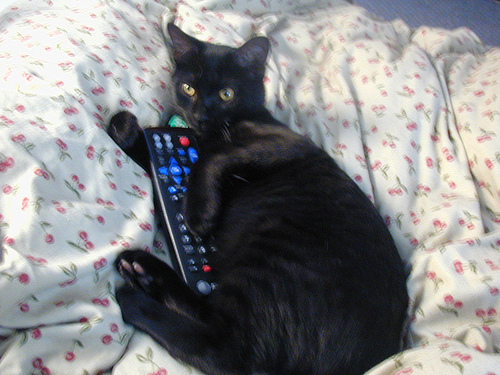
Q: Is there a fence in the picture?
A: No, there are no fences.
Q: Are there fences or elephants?
A: No, there are no fences or elephants.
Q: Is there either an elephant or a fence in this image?
A: No, there are no fences or elephants.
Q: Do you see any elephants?
A: No, there are no elephants.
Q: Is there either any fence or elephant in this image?
A: No, there are no elephants or fences.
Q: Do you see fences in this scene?
A: No, there are no fences.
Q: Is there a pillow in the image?
A: No, there are no pillows.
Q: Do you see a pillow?
A: No, there are no pillows.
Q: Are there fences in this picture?
A: No, there are no fences.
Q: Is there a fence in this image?
A: No, there are no fences.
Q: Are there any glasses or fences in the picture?
A: No, there are no fences or glasses.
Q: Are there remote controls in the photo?
A: Yes, there is a remote control.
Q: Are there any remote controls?
A: Yes, there is a remote control.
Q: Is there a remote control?
A: Yes, there is a remote control.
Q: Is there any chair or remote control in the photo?
A: Yes, there is a remote control.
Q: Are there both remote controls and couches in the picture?
A: No, there is a remote control but no couches.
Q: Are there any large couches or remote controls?
A: Yes, there is a large remote control.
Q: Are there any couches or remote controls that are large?
A: Yes, the remote control is large.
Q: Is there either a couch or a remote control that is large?
A: Yes, the remote control is large.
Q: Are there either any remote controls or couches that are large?
A: Yes, the remote control is large.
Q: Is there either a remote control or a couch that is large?
A: Yes, the remote control is large.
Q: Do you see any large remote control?
A: Yes, there is a large remote control.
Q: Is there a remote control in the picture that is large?
A: Yes, there is a remote control that is large.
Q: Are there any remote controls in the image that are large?
A: Yes, there is a remote control that is large.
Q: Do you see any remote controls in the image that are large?
A: Yes, there is a remote control that is large.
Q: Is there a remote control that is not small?
A: Yes, there is a large remote control.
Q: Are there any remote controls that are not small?
A: Yes, there is a large remote control.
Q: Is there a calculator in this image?
A: No, there are no calculators.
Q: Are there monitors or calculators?
A: No, there are no calculators or monitors.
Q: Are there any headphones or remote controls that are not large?
A: No, there is a remote control but it is large.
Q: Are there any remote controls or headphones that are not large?
A: No, there is a remote control but it is large.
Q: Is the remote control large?
A: Yes, the remote control is large.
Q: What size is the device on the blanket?
A: The remote is large.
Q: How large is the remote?
A: The remote is large.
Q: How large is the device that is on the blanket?
A: The remote is large.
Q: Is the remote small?
A: No, the remote is large.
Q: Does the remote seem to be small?
A: No, the remote is large.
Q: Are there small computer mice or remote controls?
A: No, there is a remote control but it is large.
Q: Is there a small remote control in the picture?
A: No, there is a remote control but it is large.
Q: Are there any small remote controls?
A: No, there is a remote control but it is large.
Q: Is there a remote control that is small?
A: No, there is a remote control but it is large.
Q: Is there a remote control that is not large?
A: No, there is a remote control but it is large.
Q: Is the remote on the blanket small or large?
A: The remote is large.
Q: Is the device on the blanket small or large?
A: The remote is large.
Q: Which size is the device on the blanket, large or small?
A: The remote is large.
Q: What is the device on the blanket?
A: The device is a remote control.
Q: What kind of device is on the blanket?
A: The device is a remote control.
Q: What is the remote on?
A: The remote is on the blanket.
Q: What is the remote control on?
A: The remote is on the blanket.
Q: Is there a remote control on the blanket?
A: Yes, there is a remote control on the blanket.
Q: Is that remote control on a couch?
A: No, the remote control is on the blanket.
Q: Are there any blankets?
A: Yes, there is a blanket.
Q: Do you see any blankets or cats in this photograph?
A: Yes, there is a blanket.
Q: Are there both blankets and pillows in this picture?
A: No, there is a blanket but no pillows.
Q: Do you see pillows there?
A: No, there are no pillows.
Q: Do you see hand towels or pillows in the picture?
A: No, there are no pillows or hand towels.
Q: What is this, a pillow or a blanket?
A: This is a blanket.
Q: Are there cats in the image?
A: Yes, there is a cat.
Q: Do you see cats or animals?
A: Yes, there is a cat.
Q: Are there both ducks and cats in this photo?
A: No, there is a cat but no ducks.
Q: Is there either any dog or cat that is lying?
A: Yes, the cat is lying.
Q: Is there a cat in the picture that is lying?
A: Yes, there is a cat that is lying.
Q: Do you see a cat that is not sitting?
A: Yes, there is a cat that is lying .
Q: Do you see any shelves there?
A: No, there are no shelves.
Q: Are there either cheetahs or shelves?
A: No, there are no shelves or cheetahs.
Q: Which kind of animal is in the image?
A: The animal is a cat.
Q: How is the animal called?
A: The animal is a cat.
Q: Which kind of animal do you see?
A: The animal is a cat.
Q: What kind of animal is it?
A: The animal is a cat.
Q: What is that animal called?
A: This is a cat.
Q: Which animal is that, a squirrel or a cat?
A: This is a cat.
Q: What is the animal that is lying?
A: The animal is a cat.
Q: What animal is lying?
A: The animal is a cat.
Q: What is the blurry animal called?
A: The animal is a cat.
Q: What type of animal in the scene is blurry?
A: The animal is a cat.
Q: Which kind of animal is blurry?
A: The animal is a cat.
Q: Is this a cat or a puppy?
A: This is a cat.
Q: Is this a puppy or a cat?
A: This is a cat.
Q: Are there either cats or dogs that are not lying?
A: No, there is a cat but it is lying.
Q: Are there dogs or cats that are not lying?
A: No, there is a cat but it is lying.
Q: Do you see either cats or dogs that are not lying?
A: No, there is a cat but it is lying.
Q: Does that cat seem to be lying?
A: Yes, the cat is lying.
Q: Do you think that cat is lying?
A: Yes, the cat is lying.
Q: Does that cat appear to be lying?
A: Yes, the cat is lying.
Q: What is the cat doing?
A: The cat is lying.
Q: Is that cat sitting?
A: No, the cat is lying.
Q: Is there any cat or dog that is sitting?
A: No, there is a cat but it is lying.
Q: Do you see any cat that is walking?
A: No, there is a cat but it is lying.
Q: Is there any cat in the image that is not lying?
A: No, there is a cat but it is lying.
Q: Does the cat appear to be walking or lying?
A: The cat is lying.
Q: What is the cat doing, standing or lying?
A: The cat is lying.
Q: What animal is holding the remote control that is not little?
A: The cat is holding the remote.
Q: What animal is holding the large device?
A: The cat is holding the remote.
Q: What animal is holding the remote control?
A: The cat is holding the remote.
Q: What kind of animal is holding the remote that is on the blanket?
A: The animal is a cat.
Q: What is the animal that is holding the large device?
A: The animal is a cat.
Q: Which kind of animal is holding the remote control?
A: The animal is a cat.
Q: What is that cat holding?
A: The cat is holding the remote.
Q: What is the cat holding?
A: The cat is holding the remote.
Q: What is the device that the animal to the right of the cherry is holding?
A: The device is a remote control.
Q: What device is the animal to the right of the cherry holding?
A: The cat is holding the remote control.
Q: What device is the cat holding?
A: The cat is holding the remote control.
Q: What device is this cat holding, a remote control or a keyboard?
A: The cat is holding a remote control.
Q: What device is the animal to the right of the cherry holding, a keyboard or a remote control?
A: The cat is holding a remote control.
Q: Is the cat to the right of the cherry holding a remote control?
A: Yes, the cat is holding a remote control.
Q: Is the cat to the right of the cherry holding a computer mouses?
A: No, the cat is holding a remote control.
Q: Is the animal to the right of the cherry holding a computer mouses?
A: No, the cat is holding a remote control.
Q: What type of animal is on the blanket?
A: The animal is a cat.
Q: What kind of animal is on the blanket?
A: The animal is a cat.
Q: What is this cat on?
A: The cat is on the blanket.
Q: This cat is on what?
A: The cat is on the blanket.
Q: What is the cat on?
A: The cat is on the blanket.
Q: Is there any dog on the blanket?
A: No, there is a cat on the blanket.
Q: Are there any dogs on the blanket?
A: No, there is a cat on the blanket.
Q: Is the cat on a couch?
A: No, the cat is on a blanket.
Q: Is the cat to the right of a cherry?
A: Yes, the cat is to the right of a cherry.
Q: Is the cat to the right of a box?
A: No, the cat is to the right of a cherry.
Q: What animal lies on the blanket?
A: The animal is a cat.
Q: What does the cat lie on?
A: The cat lies on the blanket.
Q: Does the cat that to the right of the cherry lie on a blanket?
A: Yes, the cat lies on a blanket.